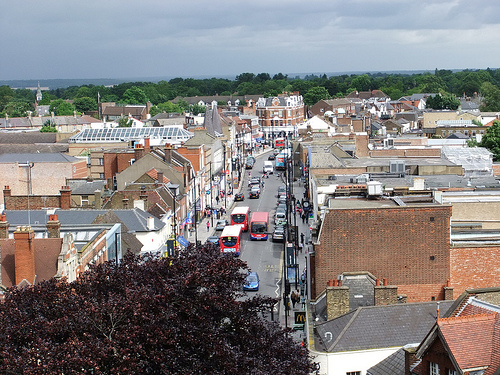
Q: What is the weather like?
A: It is cloudy.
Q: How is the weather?
A: It is cloudy.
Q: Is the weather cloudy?
A: Yes, it is cloudy.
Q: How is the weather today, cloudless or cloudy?
A: It is cloudy.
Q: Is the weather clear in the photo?
A: No, it is cloudy.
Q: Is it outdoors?
A: Yes, it is outdoors.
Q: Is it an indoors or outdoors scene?
A: It is outdoors.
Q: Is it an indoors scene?
A: No, it is outdoors.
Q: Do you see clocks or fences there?
A: No, there are no fences or clocks.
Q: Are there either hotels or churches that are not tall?
A: No, there is a church but it is tall.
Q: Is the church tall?
A: Yes, the church is tall.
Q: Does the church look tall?
A: Yes, the church is tall.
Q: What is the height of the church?
A: The church is tall.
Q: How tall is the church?
A: The church is tall.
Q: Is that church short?
A: No, the church is tall.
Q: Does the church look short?
A: No, the church is tall.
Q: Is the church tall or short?
A: The church is tall.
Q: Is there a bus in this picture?
A: Yes, there are buses.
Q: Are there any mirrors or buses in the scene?
A: Yes, there are buses.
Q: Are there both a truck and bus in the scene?
A: No, there are buses but no trucks.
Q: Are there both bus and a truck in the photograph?
A: No, there are buses but no trucks.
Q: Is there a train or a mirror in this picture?
A: No, there are no trains or mirrors.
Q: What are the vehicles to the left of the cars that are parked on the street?
A: The vehicles are buses.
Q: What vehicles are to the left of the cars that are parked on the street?
A: The vehicles are buses.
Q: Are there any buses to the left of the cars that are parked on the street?
A: Yes, there are buses to the left of the cars.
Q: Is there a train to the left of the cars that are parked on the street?
A: No, there are buses to the left of the cars.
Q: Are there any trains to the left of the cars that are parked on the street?
A: No, there are buses to the left of the cars.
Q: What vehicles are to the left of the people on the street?
A: The vehicles are buses.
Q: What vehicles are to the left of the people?
A: The vehicles are buses.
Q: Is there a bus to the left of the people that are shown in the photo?
A: Yes, there are buses to the left of the people.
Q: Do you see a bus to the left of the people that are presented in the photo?
A: Yes, there are buses to the left of the people.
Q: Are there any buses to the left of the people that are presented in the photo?
A: Yes, there are buses to the left of the people.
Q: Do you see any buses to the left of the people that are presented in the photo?
A: Yes, there are buses to the left of the people.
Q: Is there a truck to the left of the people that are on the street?
A: No, there are buses to the left of the people.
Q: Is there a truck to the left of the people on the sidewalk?
A: No, there are buses to the left of the people.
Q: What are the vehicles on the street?
A: The vehicles are buses.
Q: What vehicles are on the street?
A: The vehicles are buses.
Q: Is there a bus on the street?
A: Yes, there are buses on the street.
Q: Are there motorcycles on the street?
A: No, there are buses on the street.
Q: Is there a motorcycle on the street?
A: No, there are buses on the street.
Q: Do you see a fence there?
A: No, there are no fences.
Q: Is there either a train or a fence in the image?
A: No, there are no fences or trains.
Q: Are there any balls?
A: No, there are no balls.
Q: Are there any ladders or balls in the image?
A: No, there are no balls or ladders.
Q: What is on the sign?
A: The letter is on the sign.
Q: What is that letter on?
A: The letter is on the sign.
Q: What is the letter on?
A: The letter is on the sign.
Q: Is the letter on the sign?
A: Yes, the letter is on the sign.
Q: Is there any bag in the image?
A: No, there are no bags.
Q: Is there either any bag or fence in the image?
A: No, there are no bags or fences.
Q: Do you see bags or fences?
A: No, there are no bags or fences.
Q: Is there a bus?
A: Yes, there is a bus.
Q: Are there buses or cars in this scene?
A: Yes, there is a bus.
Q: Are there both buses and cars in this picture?
A: Yes, there are both a bus and a car.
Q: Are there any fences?
A: No, there are no fences.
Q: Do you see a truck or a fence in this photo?
A: No, there are no fences or trucks.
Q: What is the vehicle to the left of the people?
A: The vehicle is a bus.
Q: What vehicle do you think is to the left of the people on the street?
A: The vehicle is a bus.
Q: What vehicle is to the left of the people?
A: The vehicle is a bus.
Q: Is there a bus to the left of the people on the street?
A: Yes, there is a bus to the left of the people.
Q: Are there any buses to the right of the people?
A: No, the bus is to the left of the people.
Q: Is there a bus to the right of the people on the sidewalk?
A: No, the bus is to the left of the people.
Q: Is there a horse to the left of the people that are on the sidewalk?
A: No, there is a bus to the left of the people.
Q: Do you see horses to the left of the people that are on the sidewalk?
A: No, there is a bus to the left of the people.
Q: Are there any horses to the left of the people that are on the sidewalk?
A: No, there is a bus to the left of the people.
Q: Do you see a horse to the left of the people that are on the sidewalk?
A: No, there is a bus to the left of the people.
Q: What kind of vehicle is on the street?
A: The vehicle is a bus.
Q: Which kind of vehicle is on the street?
A: The vehicle is a bus.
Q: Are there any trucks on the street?
A: No, there is a bus on the street.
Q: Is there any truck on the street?
A: No, there is a bus on the street.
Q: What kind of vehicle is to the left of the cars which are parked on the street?
A: The vehicle is a bus.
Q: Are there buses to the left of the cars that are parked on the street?
A: Yes, there is a bus to the left of the cars.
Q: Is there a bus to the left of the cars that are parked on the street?
A: Yes, there is a bus to the left of the cars.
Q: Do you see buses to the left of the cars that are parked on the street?
A: Yes, there is a bus to the left of the cars.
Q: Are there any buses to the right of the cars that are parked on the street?
A: No, the bus is to the left of the cars.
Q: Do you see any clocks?
A: No, there are no clocks.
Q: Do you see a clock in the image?
A: No, there are no clocks.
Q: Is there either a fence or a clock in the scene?
A: No, there are no clocks or fences.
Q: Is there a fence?
A: No, there are no fences.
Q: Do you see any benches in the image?
A: No, there are no benches.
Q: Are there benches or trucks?
A: No, there are no benches or trucks.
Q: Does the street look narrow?
A: Yes, the street is narrow.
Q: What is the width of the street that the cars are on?
A: The street is narrow.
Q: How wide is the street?
A: The street is narrow.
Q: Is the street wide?
A: No, the street is narrow.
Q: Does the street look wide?
A: No, the street is narrow.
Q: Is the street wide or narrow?
A: The street is narrow.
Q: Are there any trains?
A: No, there are no trains.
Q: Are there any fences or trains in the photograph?
A: No, there are no trains or fences.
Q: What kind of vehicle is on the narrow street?
A: The vehicle is a car.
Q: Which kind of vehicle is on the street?
A: The vehicle is a car.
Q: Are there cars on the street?
A: Yes, there is a car on the street.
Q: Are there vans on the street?
A: No, there is a car on the street.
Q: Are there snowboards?
A: No, there are no snowboards.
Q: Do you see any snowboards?
A: No, there are no snowboards.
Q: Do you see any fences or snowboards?
A: No, there are no snowboards or fences.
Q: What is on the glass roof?
A: The chimney is on the roof.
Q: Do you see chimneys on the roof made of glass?
A: Yes, there is a chimney on the roof.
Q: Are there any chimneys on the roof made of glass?
A: Yes, there is a chimney on the roof.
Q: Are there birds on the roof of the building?
A: No, there is a chimney on the roof.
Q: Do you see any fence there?
A: No, there are no fences.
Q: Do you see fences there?
A: No, there are no fences.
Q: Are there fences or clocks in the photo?
A: No, there are no fences or clocks.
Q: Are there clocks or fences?
A: No, there are no fences or clocks.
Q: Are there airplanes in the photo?
A: No, there are no airplanes.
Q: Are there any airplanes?
A: No, there are no airplanes.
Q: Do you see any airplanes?
A: No, there are no airplanes.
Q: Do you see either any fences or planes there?
A: No, there are no planes or fences.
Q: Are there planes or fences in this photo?
A: No, there are no planes or fences.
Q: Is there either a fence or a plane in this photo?
A: No, there are no airplanes or fences.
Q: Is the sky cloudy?
A: Yes, the sky is cloudy.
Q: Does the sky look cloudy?
A: Yes, the sky is cloudy.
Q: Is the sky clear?
A: No, the sky is cloudy.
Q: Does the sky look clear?
A: No, the sky is cloudy.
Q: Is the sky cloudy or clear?
A: The sky is cloudy.